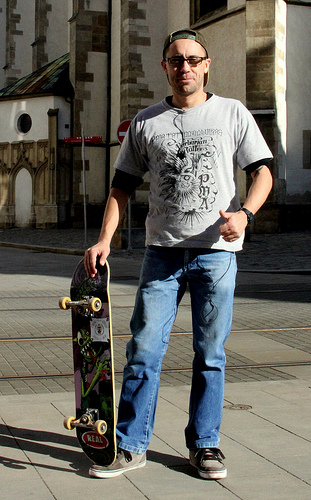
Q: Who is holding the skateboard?
A: The man.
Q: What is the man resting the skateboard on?
A: His foot.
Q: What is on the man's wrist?
A: Watch.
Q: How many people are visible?
A: One.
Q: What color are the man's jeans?
A: Blue.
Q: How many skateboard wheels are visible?
A: Four.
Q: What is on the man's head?
A: Hat.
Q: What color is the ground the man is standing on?
A: Gray.